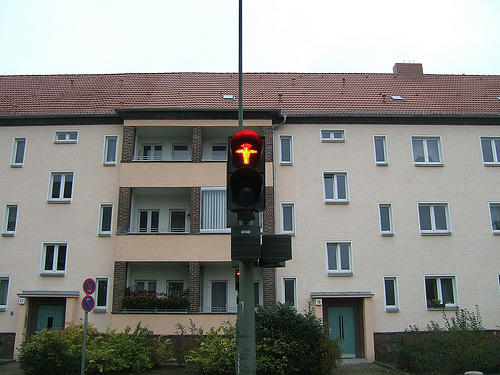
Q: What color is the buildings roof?
A: Red.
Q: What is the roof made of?
A: Tiles.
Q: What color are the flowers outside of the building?
A: Yellow.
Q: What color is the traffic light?
A: Red.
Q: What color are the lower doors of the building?
A: Green.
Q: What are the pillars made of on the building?
A: Brick.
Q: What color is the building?
A: Light tan.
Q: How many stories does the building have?
A: Four.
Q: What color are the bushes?
A: Green.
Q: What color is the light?
A: Red.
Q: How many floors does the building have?
A: Three.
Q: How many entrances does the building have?
A: Two.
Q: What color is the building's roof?
A: Red.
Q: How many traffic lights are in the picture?
A: One.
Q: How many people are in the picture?
A: Zero.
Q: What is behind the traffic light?
A: Shrubbery.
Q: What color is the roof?
A: Brown.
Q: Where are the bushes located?
A: Behind the traffic light.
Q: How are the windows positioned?
A: Vertically.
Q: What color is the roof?
A: Brown.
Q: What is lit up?
A: A street light.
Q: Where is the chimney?
A: On the roof.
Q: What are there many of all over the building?
A: Windows.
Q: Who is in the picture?
A: No one.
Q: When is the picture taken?
A: Day time.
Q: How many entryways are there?
A: Two.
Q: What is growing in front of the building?
A: Bushes.